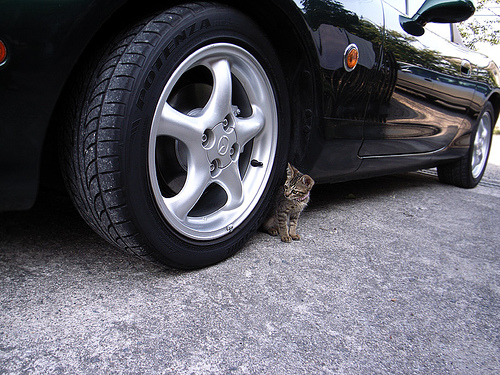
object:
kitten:
[258, 163, 315, 246]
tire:
[437, 100, 497, 190]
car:
[1, 0, 500, 273]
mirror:
[399, 0, 475, 35]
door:
[358, 0, 479, 162]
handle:
[459, 59, 472, 75]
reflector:
[342, 43, 360, 74]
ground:
[1, 135, 500, 375]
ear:
[286, 164, 299, 177]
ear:
[302, 176, 315, 191]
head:
[281, 162, 314, 204]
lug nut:
[201, 133, 209, 142]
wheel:
[59, 1, 291, 272]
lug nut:
[223, 119, 231, 128]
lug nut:
[209, 162, 217, 175]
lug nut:
[229, 147, 237, 155]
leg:
[277, 209, 296, 244]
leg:
[289, 217, 297, 242]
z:
[187, 22, 200, 39]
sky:
[457, 0, 500, 58]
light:
[0, 39, 9, 68]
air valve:
[250, 159, 264, 166]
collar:
[296, 191, 310, 201]